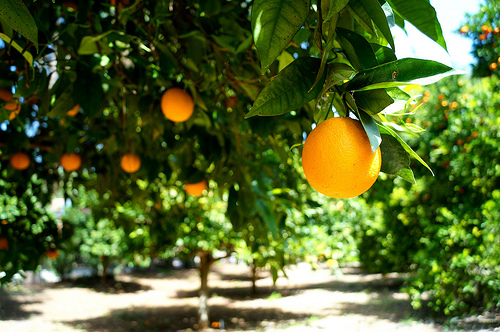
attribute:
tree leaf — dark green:
[243, 53, 330, 118]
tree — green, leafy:
[398, 190, 498, 326]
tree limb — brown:
[219, 54, 248, 93]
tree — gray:
[172, 205, 232, 330]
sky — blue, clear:
[441, 5, 449, 15]